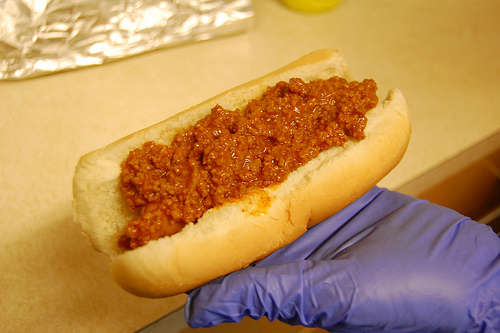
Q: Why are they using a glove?
A: To not spread germs.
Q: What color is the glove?
A: Blue.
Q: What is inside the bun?
A: Sloppy joe.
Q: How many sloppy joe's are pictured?
A: One.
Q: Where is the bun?
A: In the person's hand.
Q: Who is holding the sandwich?
A: Someone with a blue glove.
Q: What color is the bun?
A: Tan.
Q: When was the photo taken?
A: Mealtime.